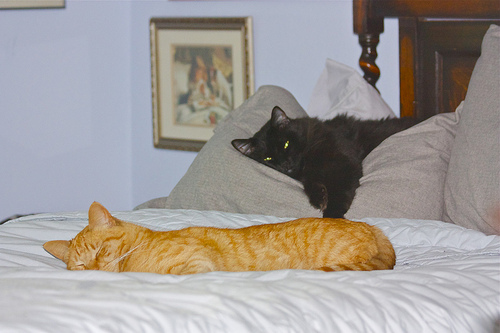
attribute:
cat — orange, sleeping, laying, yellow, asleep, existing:
[42, 202, 395, 274]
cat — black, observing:
[231, 105, 424, 217]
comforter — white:
[1, 209, 499, 332]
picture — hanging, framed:
[149, 17, 254, 154]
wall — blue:
[128, 2, 400, 208]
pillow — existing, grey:
[168, 84, 460, 222]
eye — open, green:
[285, 140, 290, 147]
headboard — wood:
[352, 1, 498, 117]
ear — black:
[232, 137, 253, 157]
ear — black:
[272, 105, 286, 121]